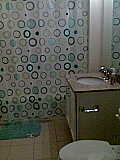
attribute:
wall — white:
[8, 3, 66, 89]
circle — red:
[28, 95, 35, 102]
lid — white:
[58, 138, 116, 159]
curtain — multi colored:
[0, 0, 90, 120]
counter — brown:
[65, 72, 116, 88]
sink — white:
[77, 75, 105, 84]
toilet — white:
[57, 138, 116, 159]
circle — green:
[16, 104, 24, 111]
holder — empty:
[79, 103, 97, 118]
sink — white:
[67, 65, 106, 93]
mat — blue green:
[0, 121, 41, 139]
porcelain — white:
[56, 137, 119, 159]